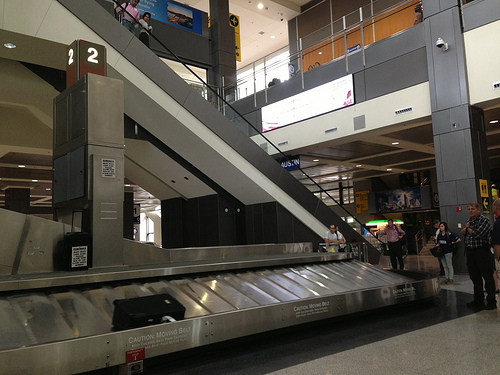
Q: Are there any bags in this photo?
A: Yes, there is a bag.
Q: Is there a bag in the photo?
A: Yes, there is a bag.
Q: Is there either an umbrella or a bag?
A: Yes, there is a bag.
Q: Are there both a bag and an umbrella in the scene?
A: No, there is a bag but no umbrellas.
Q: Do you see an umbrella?
A: No, there are no umbrellas.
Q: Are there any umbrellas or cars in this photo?
A: No, there are no umbrellas or cars.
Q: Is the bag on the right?
A: Yes, the bag is on the right of the image.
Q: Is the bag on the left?
A: No, the bag is on the right of the image.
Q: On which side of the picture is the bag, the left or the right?
A: The bag is on the right of the image.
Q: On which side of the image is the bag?
A: The bag is on the right of the image.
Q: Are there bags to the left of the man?
A: Yes, there is a bag to the left of the man.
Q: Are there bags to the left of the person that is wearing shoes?
A: Yes, there is a bag to the left of the man.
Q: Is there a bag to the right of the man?
A: No, the bag is to the left of the man.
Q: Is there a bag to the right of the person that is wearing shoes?
A: No, the bag is to the left of the man.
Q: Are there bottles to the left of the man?
A: No, there is a bag to the left of the man.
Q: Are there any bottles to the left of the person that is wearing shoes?
A: No, there is a bag to the left of the man.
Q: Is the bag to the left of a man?
A: Yes, the bag is to the left of a man.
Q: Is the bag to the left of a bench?
A: No, the bag is to the left of a man.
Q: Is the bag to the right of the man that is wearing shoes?
A: No, the bag is to the left of the man.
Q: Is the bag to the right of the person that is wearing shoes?
A: No, the bag is to the left of the man.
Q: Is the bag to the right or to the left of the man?
A: The bag is to the left of the man.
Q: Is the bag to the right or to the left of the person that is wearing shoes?
A: The bag is to the left of the man.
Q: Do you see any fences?
A: No, there are no fences.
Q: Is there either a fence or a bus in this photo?
A: No, there are no fences or buses.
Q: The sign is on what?
A: The sign is on the wall.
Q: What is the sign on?
A: The sign is on the wall.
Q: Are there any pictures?
A: No, there are no pictures.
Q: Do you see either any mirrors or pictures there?
A: No, there are no pictures or mirrors.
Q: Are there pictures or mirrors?
A: No, there are no pictures or mirrors.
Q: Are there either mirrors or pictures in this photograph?
A: No, there are no pictures or mirrors.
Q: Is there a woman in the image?
A: Yes, there is a woman.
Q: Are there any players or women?
A: Yes, there is a woman.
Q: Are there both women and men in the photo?
A: Yes, there are both a woman and a man.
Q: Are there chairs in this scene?
A: No, there are no chairs.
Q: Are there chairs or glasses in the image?
A: No, there are no chairs or glasses.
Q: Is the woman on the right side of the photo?
A: Yes, the woman is on the right of the image.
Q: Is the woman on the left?
A: No, the woman is on the right of the image.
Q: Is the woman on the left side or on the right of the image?
A: The woman is on the right of the image.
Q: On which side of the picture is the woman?
A: The woman is on the right of the image.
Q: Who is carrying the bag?
A: The woman is carrying the bag.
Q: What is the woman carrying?
A: The woman is carrying a bag.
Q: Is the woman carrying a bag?
A: Yes, the woman is carrying a bag.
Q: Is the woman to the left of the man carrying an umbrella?
A: No, the woman is carrying a bag.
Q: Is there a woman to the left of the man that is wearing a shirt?
A: Yes, there is a woman to the left of the man.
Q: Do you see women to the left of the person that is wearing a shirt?
A: Yes, there is a woman to the left of the man.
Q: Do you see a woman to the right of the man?
A: No, the woman is to the left of the man.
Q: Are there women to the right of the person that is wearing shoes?
A: No, the woman is to the left of the man.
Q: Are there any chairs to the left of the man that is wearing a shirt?
A: No, there is a woman to the left of the man.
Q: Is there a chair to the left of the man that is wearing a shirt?
A: No, there is a woman to the left of the man.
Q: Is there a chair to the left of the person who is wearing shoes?
A: No, there is a woman to the left of the man.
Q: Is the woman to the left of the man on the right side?
A: Yes, the woman is to the left of the man.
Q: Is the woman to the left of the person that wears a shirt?
A: Yes, the woman is to the left of the man.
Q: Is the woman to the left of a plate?
A: No, the woman is to the left of the man.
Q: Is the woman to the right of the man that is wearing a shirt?
A: No, the woman is to the left of the man.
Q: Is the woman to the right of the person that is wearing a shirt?
A: No, the woman is to the left of the man.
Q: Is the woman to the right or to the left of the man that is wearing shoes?
A: The woman is to the left of the man.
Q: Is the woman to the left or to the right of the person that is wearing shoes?
A: The woman is to the left of the man.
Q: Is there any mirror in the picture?
A: No, there are no mirrors.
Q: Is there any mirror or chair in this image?
A: No, there are no mirrors or chairs.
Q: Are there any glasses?
A: No, there are no glasses.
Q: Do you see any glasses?
A: No, there are no glasses.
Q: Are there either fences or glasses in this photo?
A: No, there are no glasses or fences.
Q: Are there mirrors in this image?
A: No, there are no mirrors.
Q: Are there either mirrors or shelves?
A: No, there are no mirrors or shelves.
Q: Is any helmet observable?
A: No, there are no helmets.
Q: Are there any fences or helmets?
A: No, there are no helmets or fences.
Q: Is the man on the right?
A: Yes, the man is on the right of the image.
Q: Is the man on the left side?
A: No, the man is on the right of the image.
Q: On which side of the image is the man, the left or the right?
A: The man is on the right of the image.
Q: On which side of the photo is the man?
A: The man is on the right of the image.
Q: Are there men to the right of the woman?
A: Yes, there is a man to the right of the woman.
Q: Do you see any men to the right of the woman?
A: Yes, there is a man to the right of the woman.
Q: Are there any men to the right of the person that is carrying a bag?
A: Yes, there is a man to the right of the woman.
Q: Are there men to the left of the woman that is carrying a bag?
A: No, the man is to the right of the woman.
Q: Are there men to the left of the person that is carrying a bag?
A: No, the man is to the right of the woman.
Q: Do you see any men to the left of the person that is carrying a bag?
A: No, the man is to the right of the woman.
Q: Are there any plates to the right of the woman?
A: No, there is a man to the right of the woman.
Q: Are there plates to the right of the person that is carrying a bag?
A: No, there is a man to the right of the woman.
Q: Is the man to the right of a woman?
A: Yes, the man is to the right of a woman.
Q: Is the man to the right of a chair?
A: No, the man is to the right of a woman.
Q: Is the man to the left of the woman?
A: No, the man is to the right of the woman.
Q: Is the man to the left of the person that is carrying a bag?
A: No, the man is to the right of the woman.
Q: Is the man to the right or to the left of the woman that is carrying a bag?
A: The man is to the right of the woman.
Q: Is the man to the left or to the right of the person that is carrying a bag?
A: The man is to the right of the woman.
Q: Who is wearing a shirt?
A: The man is wearing a shirt.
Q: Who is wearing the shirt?
A: The man is wearing a shirt.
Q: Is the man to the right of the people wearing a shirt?
A: Yes, the man is wearing a shirt.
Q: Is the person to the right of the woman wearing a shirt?
A: Yes, the man is wearing a shirt.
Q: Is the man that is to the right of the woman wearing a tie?
A: No, the man is wearing a shirt.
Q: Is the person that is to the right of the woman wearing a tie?
A: No, the man is wearing a shirt.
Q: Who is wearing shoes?
A: The man is wearing shoes.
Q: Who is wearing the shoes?
A: The man is wearing shoes.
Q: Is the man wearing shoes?
A: Yes, the man is wearing shoes.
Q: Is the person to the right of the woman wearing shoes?
A: Yes, the man is wearing shoes.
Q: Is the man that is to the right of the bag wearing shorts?
A: No, the man is wearing shoes.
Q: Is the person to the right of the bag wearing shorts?
A: No, the man is wearing shoes.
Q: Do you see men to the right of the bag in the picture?
A: Yes, there is a man to the right of the bag.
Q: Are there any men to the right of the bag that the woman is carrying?
A: Yes, there is a man to the right of the bag.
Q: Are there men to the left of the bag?
A: No, the man is to the right of the bag.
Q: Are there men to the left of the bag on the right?
A: No, the man is to the right of the bag.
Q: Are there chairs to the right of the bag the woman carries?
A: No, there is a man to the right of the bag.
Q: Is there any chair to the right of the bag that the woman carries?
A: No, there is a man to the right of the bag.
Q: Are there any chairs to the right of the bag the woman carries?
A: No, there is a man to the right of the bag.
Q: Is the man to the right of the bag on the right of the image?
A: Yes, the man is to the right of the bag.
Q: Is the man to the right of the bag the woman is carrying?
A: Yes, the man is to the right of the bag.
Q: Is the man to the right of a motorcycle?
A: No, the man is to the right of the bag.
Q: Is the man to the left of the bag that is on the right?
A: No, the man is to the right of the bag.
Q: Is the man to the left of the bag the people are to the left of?
A: No, the man is to the right of the bag.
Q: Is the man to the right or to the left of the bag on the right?
A: The man is to the right of the bag.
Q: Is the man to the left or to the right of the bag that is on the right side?
A: The man is to the right of the bag.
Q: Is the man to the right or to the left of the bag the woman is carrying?
A: The man is to the right of the bag.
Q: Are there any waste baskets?
A: No, there are no waste baskets.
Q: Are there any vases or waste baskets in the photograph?
A: No, there are no waste baskets or vases.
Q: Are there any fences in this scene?
A: No, there are no fences.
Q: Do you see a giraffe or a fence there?
A: No, there are no fences or giraffes.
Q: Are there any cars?
A: No, there are no cars.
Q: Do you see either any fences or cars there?
A: No, there are no cars or fences.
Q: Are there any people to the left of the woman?
A: Yes, there are people to the left of the woman.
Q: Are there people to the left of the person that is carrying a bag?
A: Yes, there are people to the left of the woman.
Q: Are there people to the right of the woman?
A: No, the people are to the left of the woman.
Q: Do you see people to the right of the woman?
A: No, the people are to the left of the woman.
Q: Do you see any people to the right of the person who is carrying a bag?
A: No, the people are to the left of the woman.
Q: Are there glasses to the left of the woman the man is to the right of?
A: No, there are people to the left of the woman.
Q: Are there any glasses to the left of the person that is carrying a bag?
A: No, there are people to the left of the woman.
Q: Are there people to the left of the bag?
A: Yes, there are people to the left of the bag.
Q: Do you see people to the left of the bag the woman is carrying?
A: Yes, there are people to the left of the bag.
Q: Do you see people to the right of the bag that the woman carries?
A: No, the people are to the left of the bag.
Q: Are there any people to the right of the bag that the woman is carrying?
A: No, the people are to the left of the bag.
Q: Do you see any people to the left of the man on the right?
A: Yes, there are people to the left of the man.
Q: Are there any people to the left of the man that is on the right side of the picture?
A: Yes, there are people to the left of the man.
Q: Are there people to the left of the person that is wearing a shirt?
A: Yes, there are people to the left of the man.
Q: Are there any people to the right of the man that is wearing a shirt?
A: No, the people are to the left of the man.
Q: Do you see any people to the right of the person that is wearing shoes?
A: No, the people are to the left of the man.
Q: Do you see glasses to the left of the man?
A: No, there are people to the left of the man.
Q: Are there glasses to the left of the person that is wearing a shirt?
A: No, there are people to the left of the man.